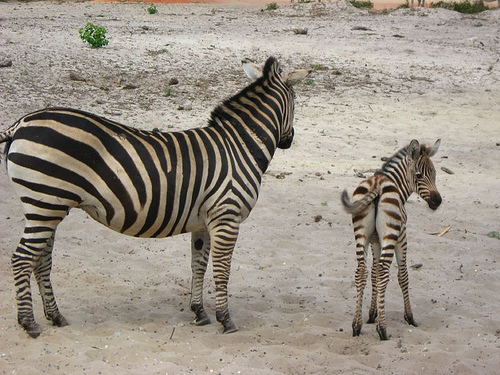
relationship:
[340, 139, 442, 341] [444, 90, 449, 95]
young zebra standing in sandy area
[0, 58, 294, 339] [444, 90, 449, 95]
zebra standing in sandy area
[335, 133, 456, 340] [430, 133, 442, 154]
young zebra has ear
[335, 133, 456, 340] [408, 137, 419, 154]
young zebra has ear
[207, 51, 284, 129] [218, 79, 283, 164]
mane in back of neck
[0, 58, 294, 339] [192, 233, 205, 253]
zebra has spot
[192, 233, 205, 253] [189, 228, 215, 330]
spot on leg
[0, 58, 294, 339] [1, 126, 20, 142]
zebra has tail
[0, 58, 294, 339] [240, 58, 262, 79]
zebra has ear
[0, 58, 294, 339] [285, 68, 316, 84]
zebra has ear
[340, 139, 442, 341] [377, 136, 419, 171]
young zebra its in back of mane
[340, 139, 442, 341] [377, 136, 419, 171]
young zebra has mane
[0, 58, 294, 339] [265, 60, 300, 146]
zebra has head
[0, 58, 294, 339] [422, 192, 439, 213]
zebra has mouth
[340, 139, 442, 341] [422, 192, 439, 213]
young zebra has mouth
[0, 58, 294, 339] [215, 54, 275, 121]
zebra has mane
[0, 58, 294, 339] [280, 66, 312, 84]
zebra has ear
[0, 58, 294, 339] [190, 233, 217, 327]
zebra has leg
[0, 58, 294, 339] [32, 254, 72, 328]
zebra has leg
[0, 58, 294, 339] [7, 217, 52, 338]
zebra has leg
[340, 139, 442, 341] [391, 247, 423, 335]
young zebra has leg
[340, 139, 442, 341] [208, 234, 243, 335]
young zebra has leg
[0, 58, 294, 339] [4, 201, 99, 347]
zebra has legs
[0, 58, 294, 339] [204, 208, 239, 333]
zebra has leg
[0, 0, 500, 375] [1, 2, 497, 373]
grey sand on ground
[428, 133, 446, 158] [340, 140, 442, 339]
ear of a young zebra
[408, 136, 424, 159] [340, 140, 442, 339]
ear of a young zebra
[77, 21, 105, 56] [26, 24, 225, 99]
plant in sand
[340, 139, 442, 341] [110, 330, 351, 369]
young zebra on sand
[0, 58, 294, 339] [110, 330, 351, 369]
zebra on sand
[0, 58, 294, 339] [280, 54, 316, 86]
zebra has ear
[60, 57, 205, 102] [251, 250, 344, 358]
rocks on sand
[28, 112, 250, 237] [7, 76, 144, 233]
stripes on rump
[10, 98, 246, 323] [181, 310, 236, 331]
zebra has feet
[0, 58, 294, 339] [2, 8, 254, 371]
zebra looking toward left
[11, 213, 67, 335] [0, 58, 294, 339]
legs of zebra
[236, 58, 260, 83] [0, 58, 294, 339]
ear of zebra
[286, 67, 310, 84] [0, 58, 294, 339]
ear of zebra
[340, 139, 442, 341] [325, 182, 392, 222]
young zebra waving tail